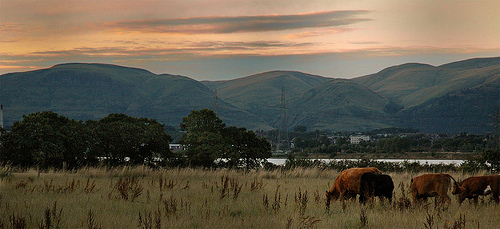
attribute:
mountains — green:
[0, 62, 496, 134]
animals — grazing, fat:
[325, 167, 499, 206]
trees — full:
[3, 115, 269, 164]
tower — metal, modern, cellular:
[275, 84, 290, 152]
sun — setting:
[1, 37, 42, 76]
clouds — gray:
[124, 9, 377, 33]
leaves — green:
[0, 113, 270, 162]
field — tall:
[0, 170, 495, 228]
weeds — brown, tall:
[112, 171, 181, 227]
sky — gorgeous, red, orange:
[1, 0, 498, 78]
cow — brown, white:
[453, 175, 499, 206]